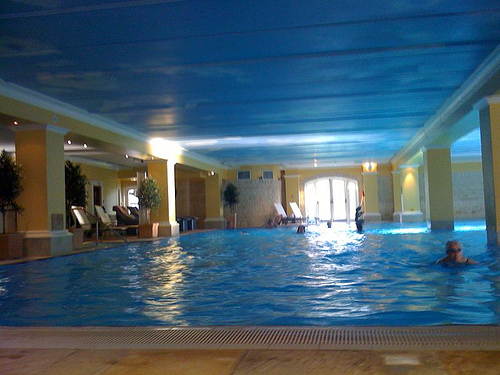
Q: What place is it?
A: It is a swimming pool.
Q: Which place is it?
A: It is a swimming pool.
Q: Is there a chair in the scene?
A: Yes, there is a chair.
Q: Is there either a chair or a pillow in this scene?
A: Yes, there is a chair.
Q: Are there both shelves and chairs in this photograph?
A: No, there is a chair but no shelves.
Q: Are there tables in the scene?
A: No, there are no tables.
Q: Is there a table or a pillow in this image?
A: No, there are no tables or pillows.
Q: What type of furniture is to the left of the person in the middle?
A: The piece of furniture is a chair.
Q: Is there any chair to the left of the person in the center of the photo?
A: Yes, there is a chair to the left of the person.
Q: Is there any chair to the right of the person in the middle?
A: No, the chair is to the left of the person.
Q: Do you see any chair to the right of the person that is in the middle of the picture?
A: No, the chair is to the left of the person.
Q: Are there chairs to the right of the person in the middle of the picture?
A: No, the chair is to the left of the person.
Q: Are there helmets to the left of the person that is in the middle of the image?
A: No, there is a chair to the left of the person.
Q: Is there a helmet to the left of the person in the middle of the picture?
A: No, there is a chair to the left of the person.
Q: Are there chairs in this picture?
A: Yes, there is a chair.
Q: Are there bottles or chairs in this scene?
A: Yes, there is a chair.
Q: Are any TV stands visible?
A: No, there are no TV stands.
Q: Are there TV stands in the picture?
A: No, there are no TV stands.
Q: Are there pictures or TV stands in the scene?
A: No, there are no TV stands or pictures.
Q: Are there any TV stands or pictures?
A: No, there are no TV stands or pictures.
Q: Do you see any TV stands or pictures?
A: No, there are no TV stands or pictures.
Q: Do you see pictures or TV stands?
A: No, there are no TV stands or pictures.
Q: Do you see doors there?
A: Yes, there are doors.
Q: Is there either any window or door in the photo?
A: Yes, there are doors.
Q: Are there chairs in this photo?
A: Yes, there is a chair.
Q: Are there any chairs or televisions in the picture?
A: Yes, there is a chair.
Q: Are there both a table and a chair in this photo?
A: No, there is a chair but no tables.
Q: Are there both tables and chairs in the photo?
A: No, there is a chair but no tables.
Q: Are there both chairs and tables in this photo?
A: No, there is a chair but no tables.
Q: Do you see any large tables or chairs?
A: Yes, there is a large chair.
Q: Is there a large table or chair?
A: Yes, there is a large chair.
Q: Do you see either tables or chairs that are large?
A: Yes, the chair is large.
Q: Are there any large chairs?
A: Yes, there is a large chair.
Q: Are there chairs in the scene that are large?
A: Yes, there is a chair that is large.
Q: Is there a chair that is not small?
A: Yes, there is a large chair.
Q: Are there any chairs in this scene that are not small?
A: Yes, there is a large chair.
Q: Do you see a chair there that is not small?
A: Yes, there is a large chair.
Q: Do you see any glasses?
A: No, there are no glasses.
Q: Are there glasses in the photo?
A: No, there are no glasses.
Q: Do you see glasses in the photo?
A: No, there are no glasses.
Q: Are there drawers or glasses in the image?
A: No, there are no glasses or drawers.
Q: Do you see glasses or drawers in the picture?
A: No, there are no glasses or drawers.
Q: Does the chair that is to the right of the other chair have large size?
A: Yes, the chair is large.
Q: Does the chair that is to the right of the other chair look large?
A: Yes, the chair is large.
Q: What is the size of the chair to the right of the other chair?
A: The chair is large.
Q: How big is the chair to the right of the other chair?
A: The chair is large.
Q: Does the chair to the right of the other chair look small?
A: No, the chair is large.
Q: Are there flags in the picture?
A: No, there are no flags.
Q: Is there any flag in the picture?
A: No, there are no flags.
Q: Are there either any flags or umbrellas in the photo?
A: No, there are no flags or umbrellas.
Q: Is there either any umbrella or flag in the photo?
A: No, there are no flags or umbrellas.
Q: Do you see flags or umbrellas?
A: No, there are no flags or umbrellas.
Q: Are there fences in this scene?
A: No, there are no fences.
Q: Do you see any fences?
A: No, there are no fences.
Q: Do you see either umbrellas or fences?
A: No, there are no fences or umbrellas.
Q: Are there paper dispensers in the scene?
A: No, there are no paper dispensers.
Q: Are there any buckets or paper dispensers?
A: No, there are no paper dispensers or buckets.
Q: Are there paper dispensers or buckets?
A: No, there are no paper dispensers or buckets.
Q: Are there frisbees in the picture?
A: No, there are no frisbees.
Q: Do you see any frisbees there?
A: No, there are no frisbees.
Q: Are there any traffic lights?
A: No, there are no traffic lights.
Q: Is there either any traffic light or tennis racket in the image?
A: No, there are no traffic lights or rackets.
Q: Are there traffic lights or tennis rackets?
A: No, there are no traffic lights or tennis rackets.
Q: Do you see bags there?
A: No, there are no bags.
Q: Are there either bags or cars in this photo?
A: No, there are no bags or cars.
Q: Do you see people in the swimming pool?
A: Yes, there is a person in the swimming pool.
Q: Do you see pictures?
A: No, there are no pictures.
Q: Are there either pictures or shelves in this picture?
A: No, there are no pictures or shelves.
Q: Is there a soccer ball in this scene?
A: No, there are no soccer balls.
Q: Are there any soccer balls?
A: No, there are no soccer balls.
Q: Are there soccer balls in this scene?
A: No, there are no soccer balls.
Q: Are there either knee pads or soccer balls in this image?
A: No, there are no soccer balls or knee pads.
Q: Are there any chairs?
A: Yes, there is a chair.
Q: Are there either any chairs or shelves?
A: Yes, there is a chair.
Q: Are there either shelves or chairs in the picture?
A: Yes, there is a chair.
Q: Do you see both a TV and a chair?
A: No, there is a chair but no televisions.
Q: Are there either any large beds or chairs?
A: Yes, there is a large chair.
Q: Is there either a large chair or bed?
A: Yes, there is a large chair.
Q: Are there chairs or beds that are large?
A: Yes, the chair is large.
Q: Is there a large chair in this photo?
A: Yes, there is a large chair.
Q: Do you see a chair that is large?
A: Yes, there is a chair that is large.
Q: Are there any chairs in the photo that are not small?
A: Yes, there is a large chair.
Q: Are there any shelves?
A: No, there are no shelves.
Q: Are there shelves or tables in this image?
A: No, there are no shelves or tables.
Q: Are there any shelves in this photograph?
A: No, there are no shelves.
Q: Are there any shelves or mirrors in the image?
A: No, there are no shelves or mirrors.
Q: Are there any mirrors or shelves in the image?
A: No, there are no shelves or mirrors.